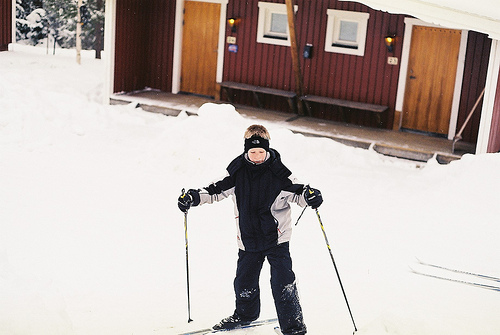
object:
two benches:
[218, 81, 387, 131]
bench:
[297, 94, 388, 129]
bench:
[215, 81, 296, 114]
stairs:
[367, 144, 437, 163]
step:
[133, 103, 181, 118]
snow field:
[0, 44, 499, 333]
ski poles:
[302, 183, 358, 332]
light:
[383, 35, 395, 54]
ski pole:
[180, 187, 194, 326]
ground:
[0, 44, 499, 334]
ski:
[412, 268, 500, 291]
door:
[398, 23, 466, 137]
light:
[224, 17, 238, 34]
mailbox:
[302, 43, 314, 59]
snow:
[0, 42, 499, 335]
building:
[106, 0, 499, 165]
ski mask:
[247, 146, 269, 163]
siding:
[224, 0, 409, 108]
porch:
[111, 68, 479, 171]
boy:
[178, 121, 327, 334]